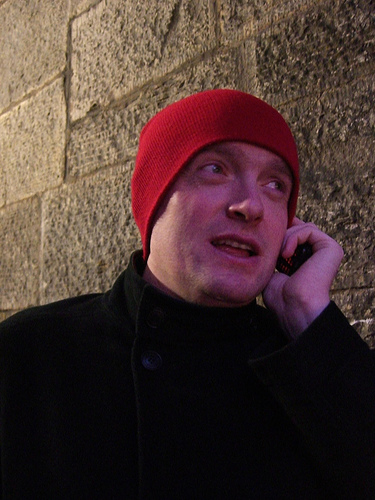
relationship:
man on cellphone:
[0, 88, 374, 500] [274, 234, 317, 275]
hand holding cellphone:
[262, 212, 346, 343] [274, 234, 317, 275]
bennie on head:
[130, 87, 297, 262] [132, 84, 299, 309]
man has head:
[0, 88, 374, 500] [132, 84, 299, 309]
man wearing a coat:
[0, 88, 374, 500] [6, 251, 374, 496]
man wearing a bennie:
[0, 88, 374, 500] [130, 87, 297, 262]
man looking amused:
[0, 88, 374, 500] [191, 144, 286, 290]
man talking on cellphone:
[0, 88, 374, 500] [274, 234, 317, 275]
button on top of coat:
[140, 345, 168, 372] [6, 251, 374, 496]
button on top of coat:
[140, 304, 171, 338] [6, 251, 374, 496]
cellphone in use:
[274, 234, 317, 275] [270, 220, 311, 281]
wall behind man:
[0, 4, 373, 331] [0, 88, 374, 500]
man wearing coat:
[0, 88, 374, 500] [6, 251, 374, 496]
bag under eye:
[200, 171, 232, 185] [198, 164, 230, 179]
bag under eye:
[266, 186, 285, 203] [264, 176, 289, 197]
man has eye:
[0, 88, 374, 500] [198, 164, 230, 179]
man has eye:
[0, 88, 374, 500] [264, 176, 289, 197]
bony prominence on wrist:
[277, 273, 316, 306] [270, 280, 333, 345]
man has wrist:
[0, 88, 374, 500] [270, 280, 333, 345]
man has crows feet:
[0, 88, 374, 500] [181, 164, 200, 186]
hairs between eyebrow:
[239, 151, 271, 174] [268, 156, 294, 181]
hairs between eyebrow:
[239, 151, 271, 174] [195, 142, 233, 162]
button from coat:
[140, 345, 168, 372] [6, 251, 374, 496]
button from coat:
[140, 304, 171, 338] [6, 251, 374, 496]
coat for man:
[6, 251, 374, 496] [0, 88, 374, 500]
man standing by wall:
[0, 88, 374, 500] [0, 4, 373, 331]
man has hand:
[0, 88, 374, 500] [262, 212, 346, 343]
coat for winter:
[6, 251, 374, 496] [2, 246, 364, 481]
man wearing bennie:
[0, 88, 374, 500] [130, 87, 297, 262]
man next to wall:
[0, 88, 374, 500] [0, 4, 373, 331]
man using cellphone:
[0, 88, 374, 500] [274, 234, 317, 275]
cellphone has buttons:
[274, 234, 317, 275] [281, 250, 298, 273]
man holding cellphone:
[0, 88, 374, 500] [274, 234, 317, 275]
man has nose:
[0, 88, 374, 500] [224, 169, 263, 223]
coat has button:
[6, 251, 374, 496] [140, 345, 168, 372]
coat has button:
[6, 251, 374, 496] [140, 304, 171, 338]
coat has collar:
[6, 251, 374, 496] [107, 255, 271, 338]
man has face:
[0, 88, 374, 500] [167, 134, 294, 298]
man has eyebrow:
[139, 88, 296, 312] [268, 156, 294, 181]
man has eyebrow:
[0, 88, 374, 500] [195, 142, 233, 162]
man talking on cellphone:
[139, 88, 296, 312] [274, 234, 317, 275]